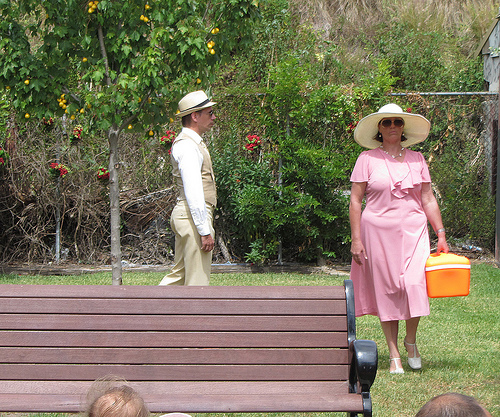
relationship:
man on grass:
[156, 89, 219, 289] [403, 320, 486, 374]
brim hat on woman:
[353, 103, 431, 147] [342, 96, 444, 381]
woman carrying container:
[342, 96, 444, 381] [418, 235, 470, 298]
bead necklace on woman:
[384, 148, 415, 183] [344, 92, 434, 362]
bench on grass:
[5, 273, 405, 415] [3, 262, 498, 415]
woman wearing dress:
[342, 96, 444, 381] [319, 133, 481, 336]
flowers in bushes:
[46, 157, 73, 178] [39, 105, 165, 211]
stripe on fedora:
[181, 97, 211, 112] [173, 89, 219, 116]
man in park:
[156, 89, 219, 289] [8, 5, 498, 414]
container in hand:
[418, 235, 470, 298] [429, 220, 450, 255]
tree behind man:
[2, 2, 249, 276] [160, 93, 221, 283]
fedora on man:
[173, 89, 219, 116] [156, 89, 219, 289]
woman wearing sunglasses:
[342, 96, 444, 381] [377, 115, 404, 128]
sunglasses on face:
[377, 115, 404, 128] [375, 113, 406, 141]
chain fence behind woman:
[429, 94, 493, 204] [342, 96, 444, 381]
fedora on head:
[173, 89, 219, 116] [177, 90, 220, 131]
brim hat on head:
[353, 103, 431, 147] [376, 120, 406, 147]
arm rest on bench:
[342, 280, 378, 410] [0, 278, 380, 415]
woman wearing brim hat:
[342, 96, 444, 381] [353, 103, 431, 147]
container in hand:
[418, 235, 470, 298] [436, 240, 448, 254]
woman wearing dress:
[342, 96, 444, 381] [349, 147, 434, 319]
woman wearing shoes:
[342, 96, 444, 381] [388, 339, 425, 376]